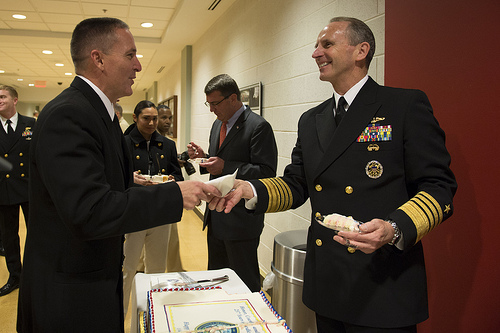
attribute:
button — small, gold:
[313, 210, 322, 220]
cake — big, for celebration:
[115, 271, 318, 331]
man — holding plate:
[210, 17, 457, 324]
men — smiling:
[13, 15, 473, 315]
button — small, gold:
[346, 243, 355, 254]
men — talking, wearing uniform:
[1, 16, 459, 331]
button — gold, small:
[343, 184, 357, 198]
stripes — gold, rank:
[241, 161, 366, 238]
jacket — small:
[247, 84, 456, 330]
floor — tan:
[1, 223, 220, 271]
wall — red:
[377, 3, 484, 330]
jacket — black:
[120, 126, 193, 232]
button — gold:
[316, 179, 365, 199]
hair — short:
[324, 6, 434, 75]